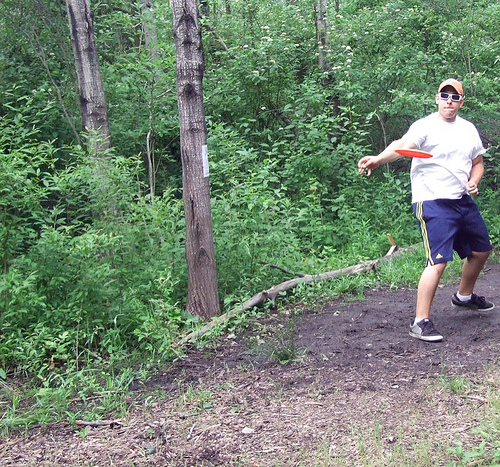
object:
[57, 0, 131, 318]
tree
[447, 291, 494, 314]
black sneakers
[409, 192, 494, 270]
shorts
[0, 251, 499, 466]
dirt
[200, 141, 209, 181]
sign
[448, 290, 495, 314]
feet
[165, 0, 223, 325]
tree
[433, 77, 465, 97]
cap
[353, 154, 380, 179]
hand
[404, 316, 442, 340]
sneakers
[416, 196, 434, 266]
stripes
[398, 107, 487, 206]
shirt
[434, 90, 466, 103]
sunglasses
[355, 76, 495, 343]
man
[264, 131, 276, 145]
foliage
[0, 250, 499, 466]
path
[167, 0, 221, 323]
trunk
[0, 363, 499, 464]
sunlight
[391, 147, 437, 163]
frisbee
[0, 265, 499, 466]
ground